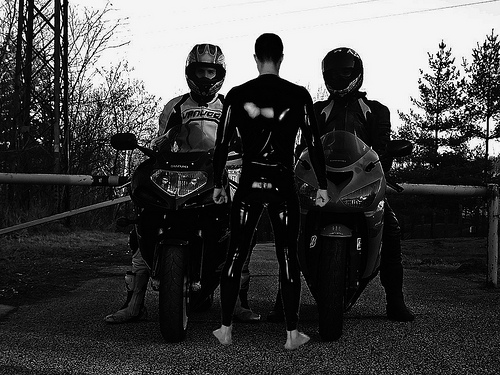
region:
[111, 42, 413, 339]
People on their motorcycles.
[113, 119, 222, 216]
Lights on the bike.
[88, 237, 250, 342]
Tire on the bike,.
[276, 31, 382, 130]
Man wearing a helmet.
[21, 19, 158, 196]
Trees in the background.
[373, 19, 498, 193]
Trees against the sky.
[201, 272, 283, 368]
Man with bare feet.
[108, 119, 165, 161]
Mirror on the bike.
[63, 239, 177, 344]
Boots on the rider.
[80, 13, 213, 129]
Sky in the background.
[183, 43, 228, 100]
motorcycle helmet on head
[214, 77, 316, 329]
black rubber body suit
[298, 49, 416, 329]
person sitting on motorcycle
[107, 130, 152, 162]
side mirror on motorcycle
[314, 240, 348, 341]
black rubber bike tire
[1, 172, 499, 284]
wooden log barrier fence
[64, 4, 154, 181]
tree with no leaves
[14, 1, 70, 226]
grey metal electrical pole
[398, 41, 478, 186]
evergreen tree by road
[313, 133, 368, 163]
wind shield on motorcycle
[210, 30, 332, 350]
A man in a black suit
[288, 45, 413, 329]
A man on a motorcycle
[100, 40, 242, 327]
A man on a motorcycle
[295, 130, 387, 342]
A dark colored motorcycle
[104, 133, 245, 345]
A dark colored motorcycle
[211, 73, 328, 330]
A spandex full body suit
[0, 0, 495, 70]
some power lines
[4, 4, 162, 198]
A small group of trees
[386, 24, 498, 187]
A small group of trees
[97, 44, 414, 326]
A pair of people on motorcycles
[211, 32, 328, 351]
The back of a guy in shiny black clothes.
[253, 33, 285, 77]
Back of the head of a man turned around.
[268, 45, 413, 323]
A man sitting on a bike to the right of a man.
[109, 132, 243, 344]
Bike with large triangle headlight on the front.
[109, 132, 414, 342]
Two motor bikes in the photo.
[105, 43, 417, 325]
Two men sitting on bikes.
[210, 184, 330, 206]
Hands on a man turned around backwards.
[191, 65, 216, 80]
Visible face through a helmet on the man on the left.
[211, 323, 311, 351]
Bare feet on a man standing between two bikes.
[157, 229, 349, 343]
Two black front tires on bikes.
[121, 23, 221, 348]
This is a person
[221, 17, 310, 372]
This is a person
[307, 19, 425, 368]
This is a person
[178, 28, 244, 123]
This is a helmet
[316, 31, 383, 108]
This is a helmet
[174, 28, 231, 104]
Head of a person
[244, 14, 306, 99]
Head of a person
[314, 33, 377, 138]
Head of a person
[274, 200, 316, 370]
Leg of a person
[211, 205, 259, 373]
Leg of a person